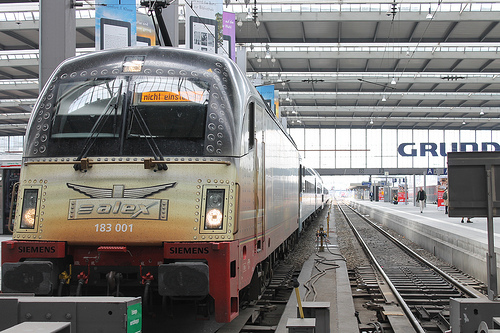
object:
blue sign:
[428, 168, 434, 174]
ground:
[397, 160, 403, 185]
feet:
[462, 219, 466, 223]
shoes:
[461, 220, 465, 223]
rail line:
[334, 198, 490, 331]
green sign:
[127, 302, 141, 333]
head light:
[194, 183, 228, 237]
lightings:
[277, 42, 375, 52]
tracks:
[253, 196, 494, 331]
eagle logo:
[67, 183, 175, 198]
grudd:
[395, 142, 499, 159]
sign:
[448, 149, 496, 218]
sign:
[142, 90, 202, 102]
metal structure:
[1, 294, 146, 331]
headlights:
[20, 184, 38, 230]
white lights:
[406, 50, 409, 57]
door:
[250, 105, 269, 254]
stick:
[126, 303, 143, 330]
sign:
[89, 0, 139, 48]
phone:
[100, 20, 127, 48]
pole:
[292, 287, 306, 319]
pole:
[483, 163, 498, 302]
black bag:
[437, 185, 445, 205]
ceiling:
[236, 10, 499, 45]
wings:
[66, 181, 175, 200]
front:
[1, 45, 235, 322]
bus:
[5, 45, 330, 328]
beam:
[39, 0, 74, 94]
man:
[415, 186, 426, 212]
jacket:
[415, 190, 427, 202]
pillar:
[35, 0, 76, 81]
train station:
[0, 0, 497, 333]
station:
[0, 0, 499, 332]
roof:
[0, 3, 495, 133]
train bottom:
[0, 218, 260, 327]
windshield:
[49, 73, 203, 158]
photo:
[2, 0, 500, 332]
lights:
[390, 78, 398, 86]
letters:
[129, 319, 140, 326]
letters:
[143, 93, 190, 101]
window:
[43, 73, 210, 157]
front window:
[24, 52, 236, 156]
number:
[94, 223, 133, 233]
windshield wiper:
[129, 106, 168, 171]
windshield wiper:
[74, 92, 121, 161]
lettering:
[131, 310, 135, 316]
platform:
[335, 170, 497, 298]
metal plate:
[448, 148, 500, 301]